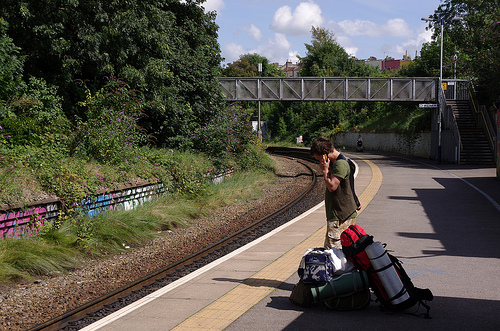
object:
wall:
[0, 165, 234, 243]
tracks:
[271, 152, 320, 165]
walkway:
[77, 147, 500, 331]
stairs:
[460, 158, 496, 162]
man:
[307, 137, 362, 249]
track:
[25, 151, 316, 331]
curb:
[75, 199, 325, 331]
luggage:
[297, 251, 334, 284]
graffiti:
[0, 206, 47, 238]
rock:
[100, 270, 107, 274]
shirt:
[325, 153, 358, 222]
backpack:
[340, 224, 434, 319]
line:
[377, 153, 500, 211]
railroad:
[20, 150, 325, 331]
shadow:
[211, 277, 298, 292]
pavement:
[94, 151, 499, 331]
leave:
[108, 142, 112, 145]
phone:
[321, 150, 328, 162]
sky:
[179, 0, 467, 68]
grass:
[0, 149, 280, 286]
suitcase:
[309, 270, 371, 312]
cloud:
[268, 2, 323, 36]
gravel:
[235, 213, 241, 216]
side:
[168, 174, 267, 219]